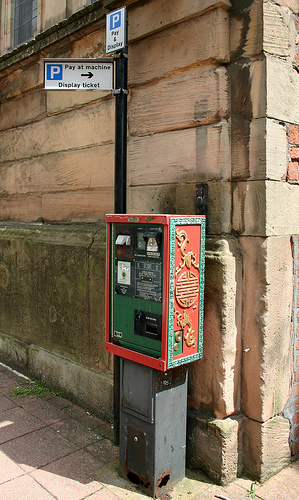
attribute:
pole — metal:
[114, 7, 127, 446]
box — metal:
[82, 188, 222, 373]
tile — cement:
[25, 446, 117, 498]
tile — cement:
[28, 441, 105, 498]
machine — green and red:
[103, 211, 204, 495]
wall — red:
[287, 233, 298, 478]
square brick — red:
[0, 390, 15, 413]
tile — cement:
[2, 426, 80, 475]